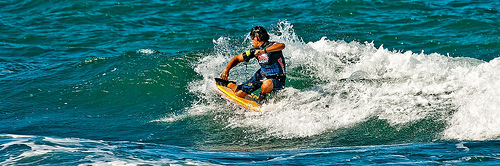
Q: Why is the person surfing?
A: For fun.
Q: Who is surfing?
A: An adult male.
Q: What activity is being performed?
A: Surfing.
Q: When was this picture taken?
A: During the daytime.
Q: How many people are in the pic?
A: One.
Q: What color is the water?
A: Blue.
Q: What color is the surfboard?
A: Yellow.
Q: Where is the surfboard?
A: Under their surfer.